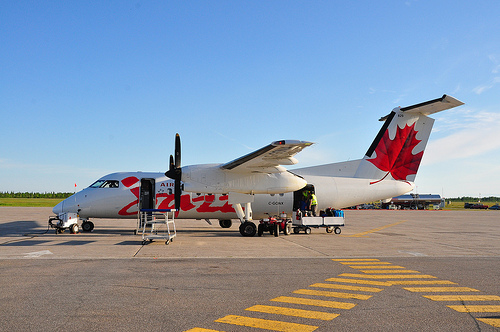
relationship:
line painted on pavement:
[455, 300, 498, 316] [174, 254, 261, 288]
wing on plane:
[189, 132, 322, 180] [42, 101, 464, 221]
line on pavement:
[257, 277, 315, 323] [182, 254, 252, 313]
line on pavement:
[375, 213, 396, 244] [89, 264, 254, 325]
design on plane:
[366, 120, 423, 187] [51, 93, 465, 237]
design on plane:
[117, 174, 232, 219] [51, 93, 465, 237]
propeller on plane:
[163, 131, 186, 213] [51, 93, 465, 237]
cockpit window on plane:
[84, 177, 126, 191] [40, 90, 469, 240]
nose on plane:
[51, 200, 68, 215] [40, 90, 469, 240]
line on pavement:
[270, 289, 358, 313] [10, 200, 481, 322]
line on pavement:
[327, 271, 381, 283] [10, 200, 481, 322]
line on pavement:
[387, 273, 461, 289] [10, 200, 481, 322]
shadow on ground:
[5, 213, 151, 250] [9, 200, 482, 317]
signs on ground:
[196, 253, 485, 321] [9, 200, 482, 317]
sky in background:
[6, 8, 483, 189] [10, 10, 484, 90]